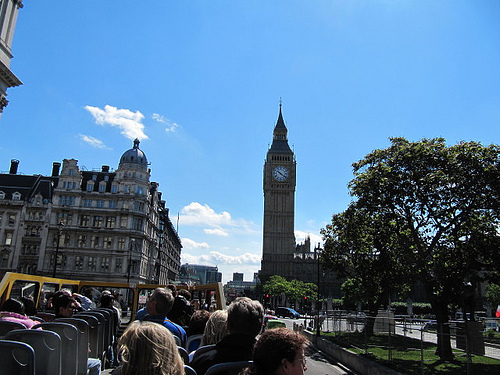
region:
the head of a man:
[253, 325, 335, 373]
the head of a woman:
[107, 319, 217, 369]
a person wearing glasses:
[286, 347, 331, 367]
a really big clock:
[251, 140, 324, 186]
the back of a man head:
[139, 282, 189, 324]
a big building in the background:
[26, 120, 220, 287]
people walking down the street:
[99, 245, 346, 367]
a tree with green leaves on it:
[326, 112, 497, 297]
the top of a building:
[38, 107, 200, 194]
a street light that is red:
[246, 270, 343, 317]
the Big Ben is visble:
[237, 86, 329, 302]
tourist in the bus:
[109, 258, 298, 373]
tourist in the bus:
[16, 257, 139, 356]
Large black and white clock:
[264, 161, 296, 191]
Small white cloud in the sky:
[149, 101, 191, 146]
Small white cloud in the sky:
[83, 95, 147, 147]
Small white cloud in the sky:
[68, 124, 111, 159]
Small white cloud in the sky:
[180, 191, 240, 249]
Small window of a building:
[102, 209, 114, 229]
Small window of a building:
[91, 213, 106, 237]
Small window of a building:
[75, 208, 87, 233]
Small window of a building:
[112, 234, 127, 256]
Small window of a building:
[65, 227, 143, 255]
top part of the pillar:
[250, 100, 301, 135]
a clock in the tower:
[258, 155, 301, 192]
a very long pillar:
[236, 96, 316, 302]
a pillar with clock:
[241, 95, 326, 295]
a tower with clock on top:
[241, 98, 313, 284]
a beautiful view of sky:
[9, 20, 496, 247]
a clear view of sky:
[26, 8, 493, 205]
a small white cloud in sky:
[36, 58, 181, 171]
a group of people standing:
[93, 258, 315, 373]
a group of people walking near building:
[26, 268, 307, 374]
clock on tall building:
[264, 161, 292, 186]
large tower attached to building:
[256, 94, 306, 271]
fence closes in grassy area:
[316, 303, 498, 374]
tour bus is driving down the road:
[2, 260, 274, 373]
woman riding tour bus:
[241, 325, 309, 374]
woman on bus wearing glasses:
[296, 354, 308, 367]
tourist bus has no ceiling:
[3, 264, 228, 316]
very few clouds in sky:
[76, 96, 151, 146]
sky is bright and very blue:
[1, 0, 499, 282]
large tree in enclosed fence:
[313, 126, 499, 366]